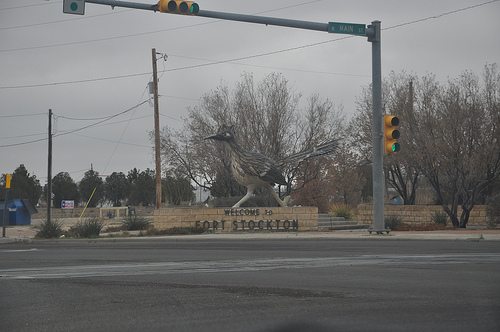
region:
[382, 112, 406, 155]
a large yellow street light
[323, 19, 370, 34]
a long green and white sign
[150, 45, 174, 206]
a tall brown light pole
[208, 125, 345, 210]
a large bird statue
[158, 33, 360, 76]
a long electrical power line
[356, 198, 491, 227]
a long brick wall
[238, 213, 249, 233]
a black capital letter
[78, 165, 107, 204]
a tall green tree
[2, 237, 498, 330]
a roadway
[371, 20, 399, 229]
a tall gray pole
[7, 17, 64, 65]
white clouds in blue sky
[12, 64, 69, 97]
white clouds in blue sky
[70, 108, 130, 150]
white clouds in blue sky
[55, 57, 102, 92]
white clouds in blue sky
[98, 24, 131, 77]
white clouds in blue sky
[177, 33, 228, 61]
white clouds in blue sky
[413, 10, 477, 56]
white clouds in blue sky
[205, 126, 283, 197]
brown bird on sign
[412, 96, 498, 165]
green tree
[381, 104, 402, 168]
yellow street signal light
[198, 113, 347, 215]
giant bird statue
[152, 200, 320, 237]
city's welcoming sign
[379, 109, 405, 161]
traffic symbol on a pole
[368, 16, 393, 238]
tall metal pole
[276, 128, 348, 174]
tail on a bird statue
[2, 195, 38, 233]
blue dumpster with a black lid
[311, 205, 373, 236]
stairs near the bird statue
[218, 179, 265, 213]
front leg of the bird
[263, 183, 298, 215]
back leg of the bird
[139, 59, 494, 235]
bear trees near the street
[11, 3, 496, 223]
Gray bleak sky kind of depressing.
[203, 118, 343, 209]
Roadrunner bird must be a symbol.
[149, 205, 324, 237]
Light brick wall with back writing.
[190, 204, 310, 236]
Welcome to Fort Stockton for visitors to see.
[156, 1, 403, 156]
Two traffic lights on the color green.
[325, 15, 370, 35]
Green sign that says Main Street.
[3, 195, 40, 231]
Steel blue dumpster for keeping things clean.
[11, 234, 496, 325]
Gray asphalt paving at intersection.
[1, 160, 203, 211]
Several junipers trees for color.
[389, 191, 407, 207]
Small blue trashcan in the park.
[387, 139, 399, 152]
glowing green traffic light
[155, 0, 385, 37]
traffic light on horizontal pole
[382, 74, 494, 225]
treea with no leaves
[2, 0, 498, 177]
cloud cover in sky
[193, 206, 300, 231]
black letters of sign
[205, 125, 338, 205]
statue of running bird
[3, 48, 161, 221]
wires suspended from pole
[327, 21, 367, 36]
green rectangle street sign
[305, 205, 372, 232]
gray steps between walls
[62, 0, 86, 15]
circle on white sign